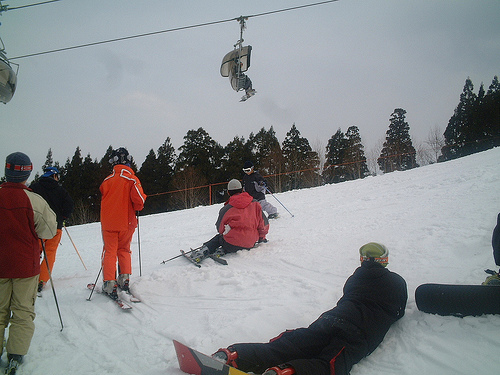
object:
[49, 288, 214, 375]
tracks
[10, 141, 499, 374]
snow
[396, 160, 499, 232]
tracks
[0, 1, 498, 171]
sky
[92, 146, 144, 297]
skier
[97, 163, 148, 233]
jacket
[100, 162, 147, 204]
stripes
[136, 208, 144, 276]
pole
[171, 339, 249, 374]
snowboard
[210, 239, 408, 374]
snowboarder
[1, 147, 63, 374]
skier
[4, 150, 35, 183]
cap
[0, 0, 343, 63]
line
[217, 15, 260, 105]
ski lift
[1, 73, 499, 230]
trees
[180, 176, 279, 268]
skier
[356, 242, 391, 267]
hat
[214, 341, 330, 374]
boots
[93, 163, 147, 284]
skisuit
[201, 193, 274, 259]
skisuit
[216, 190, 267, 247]
jacket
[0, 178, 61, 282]
jacket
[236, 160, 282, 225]
skier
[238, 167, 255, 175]
goggles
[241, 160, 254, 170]
hat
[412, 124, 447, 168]
trees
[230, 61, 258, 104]
person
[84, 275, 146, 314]
skis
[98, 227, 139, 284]
pants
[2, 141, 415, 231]
fencing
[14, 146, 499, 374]
ski area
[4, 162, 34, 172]
band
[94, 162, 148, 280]
snowsuit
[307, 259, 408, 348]
jacket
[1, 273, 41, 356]
pants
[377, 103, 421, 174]
tree